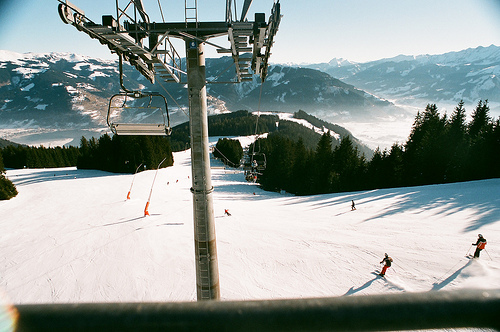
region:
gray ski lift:
[53, 5, 300, 288]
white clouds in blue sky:
[315, 17, 365, 47]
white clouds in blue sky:
[340, 0, 425, 36]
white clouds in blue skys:
[295, 15, 340, 47]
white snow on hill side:
[272, 211, 327, 257]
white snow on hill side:
[60, 232, 105, 253]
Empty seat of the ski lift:
[103, 89, 172, 137]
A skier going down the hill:
[465, 231, 491, 263]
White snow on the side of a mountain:
[31, 228, 118, 295]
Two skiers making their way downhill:
[374, 233, 491, 279]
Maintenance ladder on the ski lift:
[181, 15, 213, 296]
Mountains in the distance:
[291, 41, 496, 99]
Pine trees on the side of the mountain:
[397, 99, 499, 176]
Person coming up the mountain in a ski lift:
[247, 148, 267, 176]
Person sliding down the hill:
[346, 198, 360, 213]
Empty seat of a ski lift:
[106, 92, 175, 138]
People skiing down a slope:
[378, 227, 486, 280]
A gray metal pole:
[4, 282, 499, 329]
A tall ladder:
[187, 2, 213, 297]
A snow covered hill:
[1, 128, 498, 290]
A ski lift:
[105, 92, 171, 136]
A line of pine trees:
[255, 103, 494, 198]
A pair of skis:
[370, 267, 388, 279]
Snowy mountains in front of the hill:
[0, 43, 498, 124]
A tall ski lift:
[67, 2, 254, 299]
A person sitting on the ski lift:
[242, 150, 267, 172]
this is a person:
[367, 242, 407, 284]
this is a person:
[341, 180, 364, 222]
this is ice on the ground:
[266, 220, 321, 273]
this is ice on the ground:
[76, 233, 156, 297]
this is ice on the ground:
[253, 198, 317, 245]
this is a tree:
[297, 123, 341, 203]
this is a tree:
[335, 129, 370, 183]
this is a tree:
[370, 140, 388, 185]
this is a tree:
[403, 93, 455, 182]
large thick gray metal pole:
[180, 38, 225, 298]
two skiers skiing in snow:
[368, 226, 499, 290]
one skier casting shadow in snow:
[348, 248, 405, 296]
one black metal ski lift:
[98, 80, 177, 142]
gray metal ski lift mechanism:
[56, 3, 282, 96]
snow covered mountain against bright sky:
[308, 25, 498, 99]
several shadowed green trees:
[396, 93, 498, 188]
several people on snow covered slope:
[218, 193, 493, 283]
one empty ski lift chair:
[103, 90, 173, 137]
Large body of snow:
[261, 226, 323, 273]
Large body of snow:
[38, 223, 123, 288]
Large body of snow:
[251, 235, 323, 287]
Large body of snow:
[16, 225, 113, 282]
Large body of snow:
[268, 223, 327, 278]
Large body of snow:
[247, 229, 334, 278]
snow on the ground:
[28, 149, 488, 296]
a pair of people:
[348, 211, 499, 297]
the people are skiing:
[352, 218, 499, 289]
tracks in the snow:
[383, 265, 417, 293]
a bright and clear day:
[19, 8, 493, 290]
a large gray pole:
[171, 48, 237, 310]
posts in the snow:
[133, 148, 177, 223]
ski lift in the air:
[88, 40, 175, 146]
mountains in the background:
[5, 34, 491, 147]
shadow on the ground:
[334, 275, 377, 294]